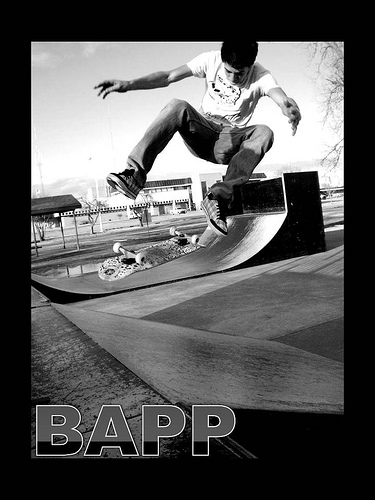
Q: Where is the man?
A: In the air.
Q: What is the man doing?
A: Skateboarding.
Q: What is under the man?
A: A skateboard.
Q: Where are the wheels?
A: On the skateboard.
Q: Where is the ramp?
A: Under the skateboard.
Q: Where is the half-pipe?
A: Behind the man.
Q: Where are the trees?
A: Behind the halfpipe.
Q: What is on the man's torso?
A: A tee shirt.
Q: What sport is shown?
A: Skateboarding.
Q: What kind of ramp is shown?
A: Half pipe.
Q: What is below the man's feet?
A: Skateboard.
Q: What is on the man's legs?
A: Pants.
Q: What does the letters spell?
A: Bapp.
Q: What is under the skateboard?
A: Ramp.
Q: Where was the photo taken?
A: Skatepark.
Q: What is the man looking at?
A: The ground.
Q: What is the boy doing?
A: A skateboarding trick.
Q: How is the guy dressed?
A: Jeans and T-shirt.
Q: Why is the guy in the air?
A: Flipping his skateboard.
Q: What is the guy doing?
A: Flipping his skateboard.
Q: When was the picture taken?
A: During the daytime.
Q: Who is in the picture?
A: Man with his skateboard.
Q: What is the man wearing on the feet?
A: Tennis shoes.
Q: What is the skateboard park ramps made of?
A: Concrete.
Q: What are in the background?
A: Houses.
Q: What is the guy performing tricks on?
A: Skateboard.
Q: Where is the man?
A: Skatepark.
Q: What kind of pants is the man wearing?
A: Jeans.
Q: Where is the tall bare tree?
A: On the far right.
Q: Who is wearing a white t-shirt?
A: The skateboarder.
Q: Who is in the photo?
A: A guy.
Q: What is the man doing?
A: Skating.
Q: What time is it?
A: Afternoon.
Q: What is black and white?
A: The picture.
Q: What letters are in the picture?
A: BAPP.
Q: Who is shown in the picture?
A: A skater.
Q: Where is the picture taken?
A: A skate park.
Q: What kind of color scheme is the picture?
A: Black and white.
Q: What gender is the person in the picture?
A: Male.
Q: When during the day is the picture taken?
A: Daytime.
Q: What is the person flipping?
A: A skateboard.